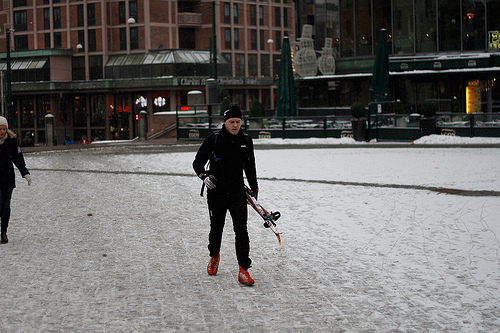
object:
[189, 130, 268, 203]
shirt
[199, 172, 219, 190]
gloves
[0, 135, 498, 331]
snow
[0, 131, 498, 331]
ground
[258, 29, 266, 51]
window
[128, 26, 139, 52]
window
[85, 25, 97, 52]
window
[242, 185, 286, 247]
black ski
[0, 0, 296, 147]
building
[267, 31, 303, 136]
umbrella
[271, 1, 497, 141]
building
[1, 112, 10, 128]
cap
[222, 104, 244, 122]
hat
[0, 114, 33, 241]
woman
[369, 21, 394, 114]
umbrella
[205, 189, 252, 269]
pants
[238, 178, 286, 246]
skateboard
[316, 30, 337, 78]
snowman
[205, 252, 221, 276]
shoe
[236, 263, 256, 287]
shoe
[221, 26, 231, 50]
window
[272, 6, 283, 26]
window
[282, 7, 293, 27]
window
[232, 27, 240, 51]
window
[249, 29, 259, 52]
window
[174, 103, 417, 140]
fence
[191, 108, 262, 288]
man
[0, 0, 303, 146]
white frame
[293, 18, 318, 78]
snowmen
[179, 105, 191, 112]
sign